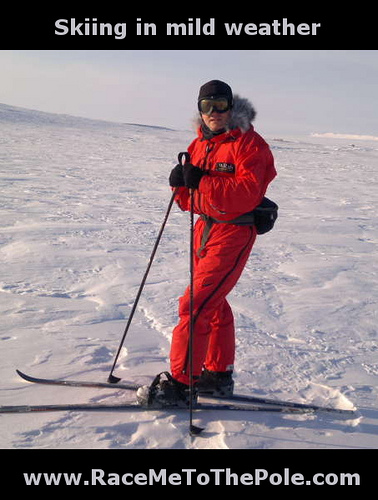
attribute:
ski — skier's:
[8, 349, 321, 403]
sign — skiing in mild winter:
[44, 4, 333, 49]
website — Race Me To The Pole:
[14, 430, 362, 495]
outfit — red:
[153, 94, 277, 403]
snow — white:
[269, 255, 339, 382]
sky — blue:
[1, 51, 369, 148]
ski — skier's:
[0, 397, 321, 420]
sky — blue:
[2, 44, 369, 140]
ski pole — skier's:
[174, 148, 205, 438]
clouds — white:
[4, 51, 376, 113]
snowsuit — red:
[169, 94, 277, 386]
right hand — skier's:
[169, 160, 184, 188]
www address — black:
[14, 466, 364, 493]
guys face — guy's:
[197, 89, 232, 132]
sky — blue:
[276, 74, 374, 108]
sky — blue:
[5, 52, 321, 124]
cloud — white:
[300, 64, 350, 109]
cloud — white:
[23, 64, 87, 92]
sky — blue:
[258, 57, 362, 129]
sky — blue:
[325, 83, 360, 107]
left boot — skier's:
[151, 370, 220, 416]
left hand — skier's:
[175, 155, 199, 189]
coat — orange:
[168, 93, 279, 221]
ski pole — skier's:
[108, 152, 189, 382]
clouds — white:
[264, 65, 376, 123]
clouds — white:
[286, 79, 362, 115]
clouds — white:
[40, 56, 367, 100]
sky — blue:
[157, 53, 189, 120]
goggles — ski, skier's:
[198, 96, 232, 114]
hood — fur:
[225, 96, 256, 131]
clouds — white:
[0, 50, 378, 136]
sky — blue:
[1, 50, 376, 135]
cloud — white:
[11, 54, 293, 130]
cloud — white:
[13, 61, 305, 133]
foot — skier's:
[190, 367, 242, 395]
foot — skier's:
[135, 372, 200, 409]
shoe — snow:
[192, 364, 241, 407]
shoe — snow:
[136, 369, 197, 406]